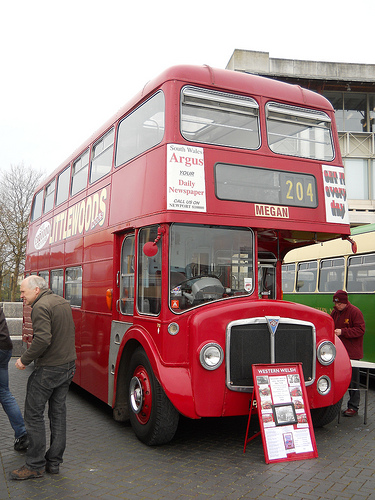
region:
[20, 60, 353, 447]
A bus is on display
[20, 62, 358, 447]
The bus is painted red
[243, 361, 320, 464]
A sign is in front of the bus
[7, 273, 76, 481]
A man is standing next to the bus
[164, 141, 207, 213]
The bus has an advertisement on it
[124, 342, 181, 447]
The bus's front wheel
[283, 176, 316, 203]
The bus's number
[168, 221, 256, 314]
This is the front window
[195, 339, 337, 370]
The bus's head lights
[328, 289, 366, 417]
A man is standing behind the bus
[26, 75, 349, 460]
double decker bus on the street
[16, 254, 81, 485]
man next to the bus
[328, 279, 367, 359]
man in a red hat next to the bus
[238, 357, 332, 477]
sign in front of the bus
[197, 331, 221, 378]
headlight on the bus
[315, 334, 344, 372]
headlight on the bus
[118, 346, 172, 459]
wheel on the bus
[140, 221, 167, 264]
mirror on the bus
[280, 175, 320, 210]
number on the bus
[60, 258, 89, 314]
window on the bus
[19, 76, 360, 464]
a red double decker bus.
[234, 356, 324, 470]
a sign in front of a red bus.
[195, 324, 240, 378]
a right front headlight.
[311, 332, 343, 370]
a left front headlight.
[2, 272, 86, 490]
A man standing near a bus.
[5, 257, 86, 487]
an old man near a bus.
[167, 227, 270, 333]
a large front wind shield.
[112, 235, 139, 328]
A side windshield on a bus.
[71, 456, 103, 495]
debris on the ground.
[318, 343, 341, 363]
a left front windshield.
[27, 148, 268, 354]
Bus is red color.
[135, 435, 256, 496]
Parking space is grey color.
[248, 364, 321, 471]
Board is red color.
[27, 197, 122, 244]
Letters are yellow color.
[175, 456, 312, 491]
Floor is made of concrete bricks.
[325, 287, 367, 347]
Man is wearing red coat and cap.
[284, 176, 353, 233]
204 is in bus board.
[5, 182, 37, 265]
Tree is without leaves.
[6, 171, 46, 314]
tree is behind the bus.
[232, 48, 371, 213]
Building is behind the bus.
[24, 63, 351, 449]
a parked red double-decker bus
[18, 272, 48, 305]
a man with white and gray hair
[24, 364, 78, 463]
a man wearing black jeans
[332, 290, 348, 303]
man wearing a red wool hat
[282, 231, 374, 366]
a green bus with a white roof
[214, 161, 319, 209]
digital display on the front of a bus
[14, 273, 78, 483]
man standing next to a red bus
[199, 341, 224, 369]
a silver headlight on a bus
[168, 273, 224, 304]
a driving wheel of a bus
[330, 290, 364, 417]
man wearing red standing next to a bus